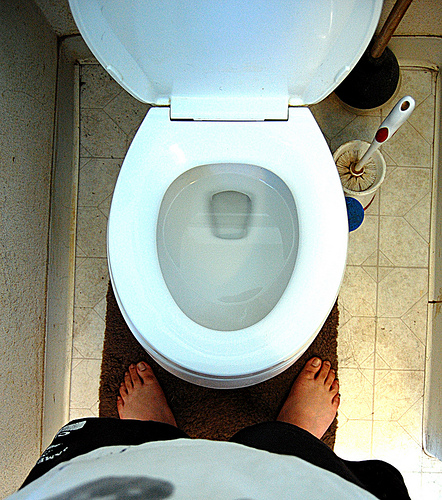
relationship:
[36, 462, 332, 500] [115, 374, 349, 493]
shirt on a person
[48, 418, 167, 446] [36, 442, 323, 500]
shorts on a person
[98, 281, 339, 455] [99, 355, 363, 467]
bathroom carpet under a persons feet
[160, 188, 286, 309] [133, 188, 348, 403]
water in a toilet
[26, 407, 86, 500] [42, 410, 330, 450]
white print on a pair of shorts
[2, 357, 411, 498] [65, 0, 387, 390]
person standing in front of toilet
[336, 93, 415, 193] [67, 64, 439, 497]
toilet brush on floor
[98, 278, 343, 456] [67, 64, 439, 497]
rug on floor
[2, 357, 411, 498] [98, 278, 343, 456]
person standing on rug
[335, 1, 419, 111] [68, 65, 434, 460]
plunger on floor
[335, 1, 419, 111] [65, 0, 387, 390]
plunger behind toilet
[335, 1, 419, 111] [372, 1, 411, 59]
plunger with handle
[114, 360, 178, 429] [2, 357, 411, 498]
left foot of person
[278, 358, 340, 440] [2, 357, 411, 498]
feet of person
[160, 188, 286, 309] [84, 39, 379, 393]
water in toilet